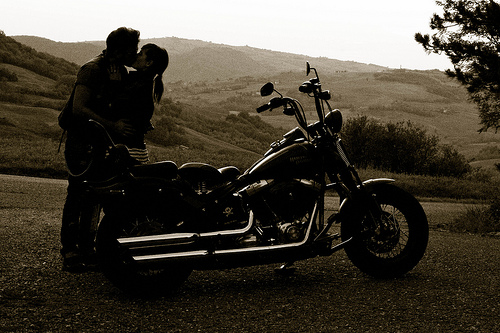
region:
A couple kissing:
[90, 21, 185, 84]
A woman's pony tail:
[152, 53, 167, 106]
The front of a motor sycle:
[232, 57, 446, 279]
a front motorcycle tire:
[326, 166, 441, 282]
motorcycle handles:
[244, 55, 361, 136]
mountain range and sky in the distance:
[166, 23, 320, 65]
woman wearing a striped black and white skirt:
[119, 129, 160, 166]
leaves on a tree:
[414, 0, 495, 147]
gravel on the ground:
[338, 291, 453, 331]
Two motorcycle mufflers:
[116, 225, 304, 267]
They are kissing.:
[54, 27, 191, 98]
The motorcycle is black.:
[85, 55, 444, 275]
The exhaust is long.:
[93, 189, 345, 269]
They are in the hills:
[20, 2, 495, 254]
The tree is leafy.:
[418, 3, 498, 156]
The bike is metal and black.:
[114, 80, 462, 295]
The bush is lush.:
[297, 90, 450, 183]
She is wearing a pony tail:
[109, 30, 186, 104]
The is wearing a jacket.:
[65, 59, 157, 147]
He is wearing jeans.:
[47, 127, 125, 282]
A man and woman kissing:
[41, 11, 194, 275]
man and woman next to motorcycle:
[56, 21, 432, 282]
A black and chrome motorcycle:
[63, 68, 442, 304]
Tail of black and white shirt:
[117, 138, 154, 168]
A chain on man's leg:
[58, 150, 88, 188]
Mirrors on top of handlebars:
[258, 68, 330, 94]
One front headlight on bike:
[326, 107, 343, 140]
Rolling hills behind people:
[10, 15, 464, 192]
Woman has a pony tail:
[152, 61, 172, 106]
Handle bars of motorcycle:
[246, 71, 349, 166]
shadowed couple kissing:
[51, 7, 175, 272]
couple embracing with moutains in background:
[48, 9, 173, 294]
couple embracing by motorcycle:
[35, 22, 435, 297]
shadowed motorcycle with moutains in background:
[172, 27, 433, 281]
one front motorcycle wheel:
[332, 174, 430, 285]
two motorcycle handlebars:
[242, 66, 352, 133]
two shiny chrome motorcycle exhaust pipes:
[106, 222, 315, 267]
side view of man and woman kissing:
[88, 24, 174, 95]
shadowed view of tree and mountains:
[378, 2, 498, 144]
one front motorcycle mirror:
[257, 77, 281, 101]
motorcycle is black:
[62, 93, 447, 260]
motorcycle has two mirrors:
[259, 55, 311, 105]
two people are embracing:
[63, 13, 173, 268]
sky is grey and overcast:
[111, 2, 448, 67]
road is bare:
[11, 177, 103, 329]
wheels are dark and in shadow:
[333, 187, 427, 289]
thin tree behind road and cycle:
[419, 8, 498, 117]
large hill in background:
[2, 8, 327, 108]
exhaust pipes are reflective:
[115, 190, 317, 279]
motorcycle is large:
[99, 57, 476, 278]